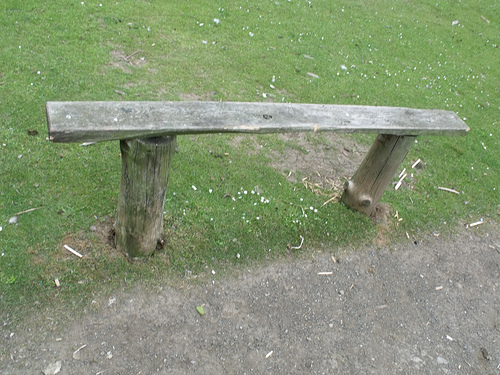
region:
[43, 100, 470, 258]
A wooden bench at a park.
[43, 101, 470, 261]
A park bench made of wood.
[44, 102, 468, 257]
A wooden park bench crudely made.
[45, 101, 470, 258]
A simple park bench made of wood.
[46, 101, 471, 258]
A simple, wooden bench.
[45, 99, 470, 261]
Simple park bench made from tree logs.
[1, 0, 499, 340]
A patch of grass along side a dirt walking path.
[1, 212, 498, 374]
A dirt walking path.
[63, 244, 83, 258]
Random debris.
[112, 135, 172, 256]
The leg of a park bench.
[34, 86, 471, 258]
wooden bench in green grass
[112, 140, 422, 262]
two posts holding up bench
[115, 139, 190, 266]
post under bench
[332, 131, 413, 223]
post holding up wooden bench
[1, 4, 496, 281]
small pieces of litter on ground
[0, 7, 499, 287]
green grass on ground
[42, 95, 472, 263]
Wooden bench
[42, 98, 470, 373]
A wooden bench next to a pathway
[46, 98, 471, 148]
A wooden plank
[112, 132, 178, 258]
A tree stump in the ground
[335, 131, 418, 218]
A tree stump in the ground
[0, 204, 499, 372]
A hiking trail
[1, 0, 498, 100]
Green grass with dandelions on it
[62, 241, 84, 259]
A piece of litter on the ground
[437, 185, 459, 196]
A piece of litter on the ground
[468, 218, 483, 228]
A piece of litter on the ground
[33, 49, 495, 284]
Wooden bench in the park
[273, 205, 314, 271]
twigs on the ground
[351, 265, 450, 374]
Gravel path beside the bench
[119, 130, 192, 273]
Log holding up the bench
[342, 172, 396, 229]
Not on the log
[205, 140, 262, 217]
The grass is short and green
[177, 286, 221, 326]
Leaf on the ground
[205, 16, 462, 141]
Trash laying on the ground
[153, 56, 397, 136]
The board is weathered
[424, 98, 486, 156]
The board is somewhat thin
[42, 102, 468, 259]
wooden bench in grass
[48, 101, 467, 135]
wooden tablet in two stumps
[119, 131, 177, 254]
stump in the left side of bench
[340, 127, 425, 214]
stump in the right side of bench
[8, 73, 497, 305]
short green grass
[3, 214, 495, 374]
pavement path next to bench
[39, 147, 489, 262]
splinters of wood in the grass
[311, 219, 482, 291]
splinters of woods in the pavement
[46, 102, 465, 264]
bench made with stumps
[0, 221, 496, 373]
pavement pathway next to green grass